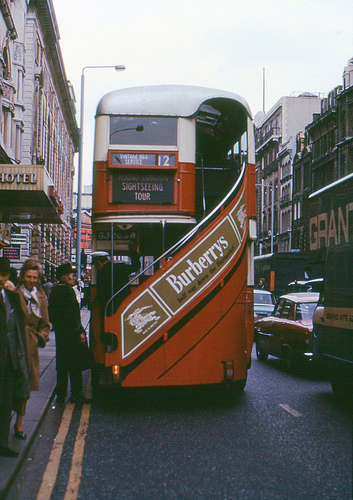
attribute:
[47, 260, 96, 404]
person — standing